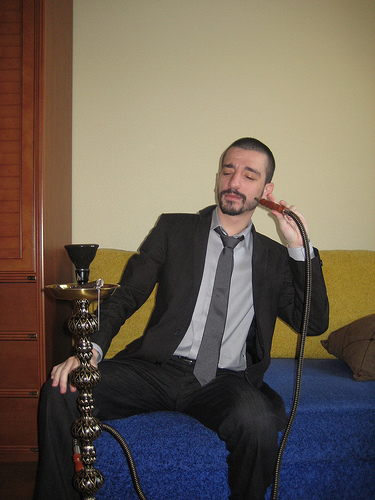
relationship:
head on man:
[213, 134, 275, 215] [33, 130, 328, 498]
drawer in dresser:
[1, 274, 42, 333] [0, 274, 42, 459]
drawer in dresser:
[1, 330, 38, 393] [0, 274, 42, 459]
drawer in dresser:
[1, 395, 39, 450] [0, 274, 42, 459]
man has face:
[33, 130, 328, 498] [202, 122, 300, 210]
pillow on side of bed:
[69, 244, 373, 361] [67, 219, 374, 459]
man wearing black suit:
[33, 130, 328, 498] [36, 204, 329, 498]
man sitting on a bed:
[37, 137, 333, 499] [60, 380, 373, 498]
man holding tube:
[33, 130, 328, 498] [259, 179, 362, 362]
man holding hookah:
[33, 130, 328, 498] [42, 240, 152, 499]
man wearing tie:
[33, 130, 328, 498] [192, 226, 243, 386]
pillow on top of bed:
[325, 313, 374, 379] [53, 307, 373, 496]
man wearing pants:
[33, 130, 328, 498] [33, 353, 280, 498]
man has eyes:
[37, 137, 333, 499] [234, 168, 264, 187]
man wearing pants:
[37, 137, 333, 499] [195, 364, 278, 442]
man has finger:
[33, 130, 328, 498] [267, 192, 277, 205]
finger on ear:
[267, 192, 277, 205] [262, 178, 272, 196]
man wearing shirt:
[33, 130, 328, 498] [173, 204, 255, 371]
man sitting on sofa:
[37, 137, 333, 499] [87, 247, 374, 497]